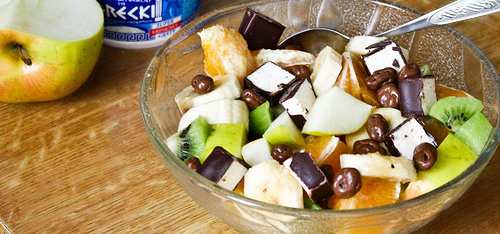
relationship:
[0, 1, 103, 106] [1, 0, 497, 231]
apple on table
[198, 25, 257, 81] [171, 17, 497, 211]
piece in salad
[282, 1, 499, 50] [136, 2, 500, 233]
spoon in bowl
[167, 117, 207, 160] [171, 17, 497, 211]
piece in salad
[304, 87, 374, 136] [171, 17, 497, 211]
slice in salad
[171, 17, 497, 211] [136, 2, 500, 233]
salad fills bowl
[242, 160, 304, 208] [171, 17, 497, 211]
piece in salad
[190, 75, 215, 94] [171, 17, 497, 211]
raisin in salad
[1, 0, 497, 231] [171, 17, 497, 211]
table with food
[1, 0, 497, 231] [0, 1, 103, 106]
table with food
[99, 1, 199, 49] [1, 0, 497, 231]
yogurt on table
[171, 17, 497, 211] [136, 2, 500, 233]
fruit in bowl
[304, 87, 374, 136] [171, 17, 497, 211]
piece in salad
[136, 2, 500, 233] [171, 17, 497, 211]
bowl with salad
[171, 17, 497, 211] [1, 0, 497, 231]
salad on table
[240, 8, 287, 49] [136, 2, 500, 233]
chocolate in bowl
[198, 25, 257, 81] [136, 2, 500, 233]
slice in bowl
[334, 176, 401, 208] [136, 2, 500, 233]
slice in bowl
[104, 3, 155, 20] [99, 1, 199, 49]
lettering on container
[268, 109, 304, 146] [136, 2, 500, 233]
wedge in bowl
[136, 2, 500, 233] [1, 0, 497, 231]
bowl on table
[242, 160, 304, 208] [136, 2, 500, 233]
banana in bowl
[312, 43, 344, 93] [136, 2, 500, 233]
banana in bowl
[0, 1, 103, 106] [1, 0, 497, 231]
apple left of table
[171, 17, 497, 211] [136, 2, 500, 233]
salad in bowl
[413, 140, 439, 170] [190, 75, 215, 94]
chocolate covers raisin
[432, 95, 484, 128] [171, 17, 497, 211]
kiwi in salad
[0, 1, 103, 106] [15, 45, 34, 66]
apple has stem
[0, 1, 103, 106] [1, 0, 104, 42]
apple has flesh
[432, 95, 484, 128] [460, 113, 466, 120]
kiwi has seed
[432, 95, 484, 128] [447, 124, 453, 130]
kiwi has seed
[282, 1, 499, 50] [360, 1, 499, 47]
spoon has handle